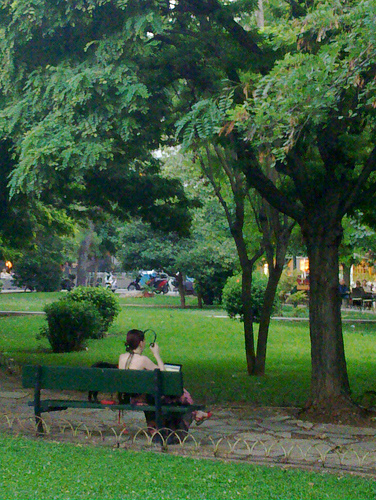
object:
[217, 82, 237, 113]
leaves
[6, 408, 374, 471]
fence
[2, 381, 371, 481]
walkway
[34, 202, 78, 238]
leaves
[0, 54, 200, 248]
tree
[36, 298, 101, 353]
bush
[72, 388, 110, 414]
legs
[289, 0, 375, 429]
tree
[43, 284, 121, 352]
bushes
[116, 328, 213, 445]
woman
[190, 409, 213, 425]
sandals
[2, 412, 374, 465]
edging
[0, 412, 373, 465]
arches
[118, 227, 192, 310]
tree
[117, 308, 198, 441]
woman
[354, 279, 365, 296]
person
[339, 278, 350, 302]
person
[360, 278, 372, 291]
person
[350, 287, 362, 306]
chair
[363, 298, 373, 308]
chair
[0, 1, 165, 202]
leaves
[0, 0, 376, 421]
brown tree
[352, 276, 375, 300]
people facing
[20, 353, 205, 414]
bench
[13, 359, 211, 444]
bench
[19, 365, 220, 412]
bench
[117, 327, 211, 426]
woman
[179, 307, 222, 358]
grass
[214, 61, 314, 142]
leaves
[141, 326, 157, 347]
head phones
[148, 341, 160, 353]
hand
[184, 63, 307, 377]
tree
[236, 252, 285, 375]
forks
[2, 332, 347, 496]
foreground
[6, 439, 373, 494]
grass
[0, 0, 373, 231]
leaves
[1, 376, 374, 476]
sidewalk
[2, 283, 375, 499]
park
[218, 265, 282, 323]
bush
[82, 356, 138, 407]
animal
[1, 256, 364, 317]
street scene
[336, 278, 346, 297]
person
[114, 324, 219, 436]
woman